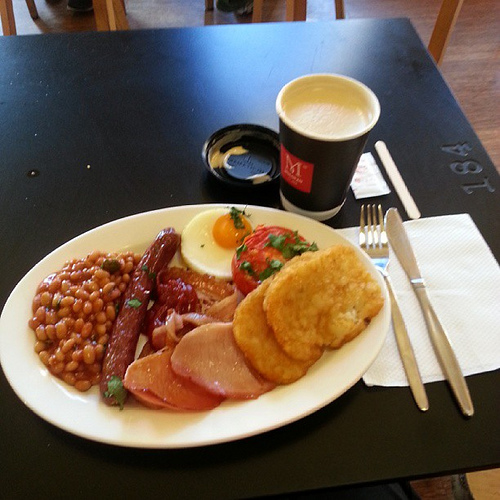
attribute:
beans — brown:
[45, 289, 106, 359]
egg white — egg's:
[180, 205, 234, 276]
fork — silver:
[355, 199, 431, 413]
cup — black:
[243, 57, 442, 244]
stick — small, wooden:
[373, 135, 423, 225]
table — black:
[0, 11, 499, 498]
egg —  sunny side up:
[167, 202, 307, 313]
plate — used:
[285, 368, 357, 390]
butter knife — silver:
[381, 210, 466, 377]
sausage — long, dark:
[115, 295, 146, 360]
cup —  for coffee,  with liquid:
[270, 61, 384, 218]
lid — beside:
[201, 119, 283, 191]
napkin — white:
[410, 181, 475, 291]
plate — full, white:
[1, 200, 391, 453]